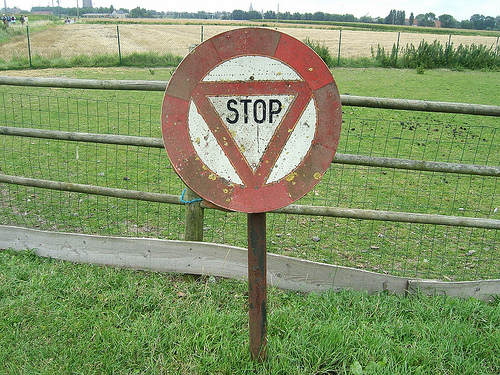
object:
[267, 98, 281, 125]
letters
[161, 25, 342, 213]
sign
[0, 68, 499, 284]
grass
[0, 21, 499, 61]
ground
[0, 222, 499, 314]
board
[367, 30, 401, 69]
bushes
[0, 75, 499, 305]
fence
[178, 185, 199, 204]
rope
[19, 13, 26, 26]
people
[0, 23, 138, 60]
field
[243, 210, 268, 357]
pole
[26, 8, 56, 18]
roof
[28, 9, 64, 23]
building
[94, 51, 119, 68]
weeds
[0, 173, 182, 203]
boards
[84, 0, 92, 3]
steeple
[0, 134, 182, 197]
wire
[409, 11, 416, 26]
trees